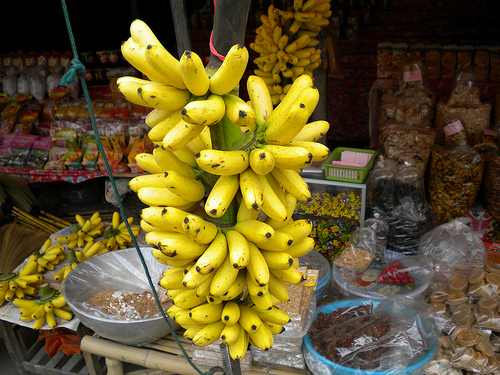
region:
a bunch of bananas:
[98, 18, 336, 365]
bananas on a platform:
[3, 208, 148, 333]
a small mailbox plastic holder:
[321, 141, 381, 190]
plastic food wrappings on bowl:
[328, 240, 435, 302]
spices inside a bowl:
[61, 240, 206, 352]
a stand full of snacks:
[1, 45, 181, 187]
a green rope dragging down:
[37, 6, 217, 372]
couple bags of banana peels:
[377, 60, 495, 227]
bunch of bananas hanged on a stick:
[112, 19, 349, 359]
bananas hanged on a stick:
[243, 3, 340, 97]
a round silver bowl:
[60, 247, 172, 349]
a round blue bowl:
[305, 296, 441, 373]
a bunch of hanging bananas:
[116, 18, 329, 363]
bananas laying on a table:
[0, 214, 145, 326]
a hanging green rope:
[56, 0, 211, 372]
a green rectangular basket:
[321, 144, 378, 182]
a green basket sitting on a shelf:
[294, 145, 376, 252]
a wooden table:
[76, 326, 301, 372]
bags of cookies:
[426, 264, 496, 374]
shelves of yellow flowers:
[296, 188, 363, 258]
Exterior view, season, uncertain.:
[3, 4, 498, 373]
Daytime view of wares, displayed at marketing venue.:
[4, 18, 499, 372]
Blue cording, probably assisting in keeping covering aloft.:
[57, 28, 118, 145]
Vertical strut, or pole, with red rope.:
[175, 19, 242, 59]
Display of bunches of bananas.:
[122, 23, 308, 352]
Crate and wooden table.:
[10, 315, 146, 370]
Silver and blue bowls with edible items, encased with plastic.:
[77, 240, 438, 372]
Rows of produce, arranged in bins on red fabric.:
[0, 50, 140, 185]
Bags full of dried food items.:
[385, 65, 485, 223]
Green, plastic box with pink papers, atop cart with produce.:
[307, 150, 369, 251]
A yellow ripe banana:
[122, 25, 340, 373]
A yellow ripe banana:
[10, 287, 72, 322]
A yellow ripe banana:
[5, 261, 37, 301]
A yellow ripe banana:
[25, 241, 62, 268]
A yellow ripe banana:
[67, 241, 95, 266]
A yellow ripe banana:
[63, 216, 102, 241]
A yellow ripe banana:
[105, 211, 145, 257]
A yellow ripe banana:
[256, 9, 343, 86]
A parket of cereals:
[387, 80, 434, 171]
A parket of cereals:
[431, 288, 486, 325]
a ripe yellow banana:
[178, 45, 211, 94]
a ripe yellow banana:
[246, 73, 271, 128]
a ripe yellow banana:
[258, 73, 313, 128]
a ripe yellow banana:
[262, 101, 307, 141]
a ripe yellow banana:
[256, 140, 311, 170]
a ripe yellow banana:
[288, 140, 328, 162]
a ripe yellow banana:
[290, 119, 332, 139]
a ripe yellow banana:
[272, 165, 312, 202]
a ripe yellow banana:
[238, 171, 263, 209]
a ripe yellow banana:
[206, 173, 236, 219]